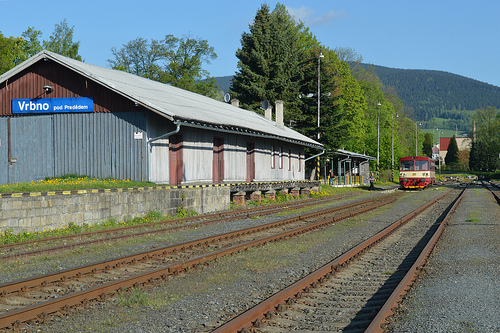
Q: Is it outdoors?
A: Yes, it is outdoors.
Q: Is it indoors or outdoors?
A: It is outdoors.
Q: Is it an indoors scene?
A: No, it is outdoors.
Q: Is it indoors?
A: No, it is outdoors.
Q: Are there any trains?
A: Yes, there is a train.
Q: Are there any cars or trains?
A: Yes, there is a train.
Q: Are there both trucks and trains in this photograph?
A: No, there is a train but no trucks.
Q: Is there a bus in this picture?
A: No, there are no buses.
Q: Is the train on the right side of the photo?
A: Yes, the train is on the right of the image.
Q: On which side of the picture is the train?
A: The train is on the right of the image.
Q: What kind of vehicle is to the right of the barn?
A: The vehicle is a train.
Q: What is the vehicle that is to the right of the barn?
A: The vehicle is a train.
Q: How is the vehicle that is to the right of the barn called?
A: The vehicle is a train.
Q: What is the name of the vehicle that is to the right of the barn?
A: The vehicle is a train.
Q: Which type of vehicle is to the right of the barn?
A: The vehicle is a train.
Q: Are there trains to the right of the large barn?
A: Yes, there is a train to the right of the barn.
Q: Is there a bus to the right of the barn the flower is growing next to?
A: No, there is a train to the right of the barn.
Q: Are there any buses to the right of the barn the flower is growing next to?
A: No, there is a train to the right of the barn.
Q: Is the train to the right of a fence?
A: No, the train is to the right of a barn.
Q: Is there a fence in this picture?
A: No, there are no fences.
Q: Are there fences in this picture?
A: No, there are no fences.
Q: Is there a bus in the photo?
A: No, there are no buses.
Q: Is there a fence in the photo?
A: No, there are no fences.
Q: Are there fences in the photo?
A: No, there are no fences.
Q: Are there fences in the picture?
A: No, there are no fences.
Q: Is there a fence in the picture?
A: No, there are no fences.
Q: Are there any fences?
A: No, there are no fences.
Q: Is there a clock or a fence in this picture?
A: No, there are no fences or clocks.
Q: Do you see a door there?
A: Yes, there are doors.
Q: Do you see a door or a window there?
A: Yes, there are doors.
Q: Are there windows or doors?
A: Yes, there are doors.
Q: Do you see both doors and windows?
A: Yes, there are both doors and windows.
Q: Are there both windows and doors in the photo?
A: Yes, there are both doors and windows.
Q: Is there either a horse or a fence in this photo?
A: No, there are no fences or horses.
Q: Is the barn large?
A: Yes, the barn is large.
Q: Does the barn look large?
A: Yes, the barn is large.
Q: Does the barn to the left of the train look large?
A: Yes, the barn is large.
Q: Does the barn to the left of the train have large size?
A: Yes, the barn is large.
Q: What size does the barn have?
A: The barn has large size.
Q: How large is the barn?
A: The barn is large.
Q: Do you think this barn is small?
A: No, the barn is large.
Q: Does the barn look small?
A: No, the barn is large.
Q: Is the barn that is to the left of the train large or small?
A: The barn is large.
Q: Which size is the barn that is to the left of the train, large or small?
A: The barn is large.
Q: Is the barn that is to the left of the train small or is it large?
A: The barn is large.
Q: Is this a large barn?
A: Yes, this is a large barn.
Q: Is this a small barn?
A: No, this is a large barn.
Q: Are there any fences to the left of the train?
A: No, there is a barn to the left of the train.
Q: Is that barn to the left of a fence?
A: No, the barn is to the left of the train.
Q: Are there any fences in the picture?
A: No, there are no fences.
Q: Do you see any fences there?
A: No, there are no fences.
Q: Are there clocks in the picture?
A: No, there are no clocks.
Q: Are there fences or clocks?
A: No, there are no clocks or fences.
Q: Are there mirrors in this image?
A: No, there are no mirrors.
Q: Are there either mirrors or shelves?
A: No, there are no mirrors or shelves.